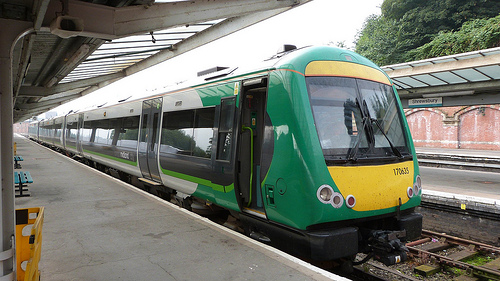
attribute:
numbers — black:
[390, 165, 410, 176]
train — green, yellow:
[26, 43, 427, 261]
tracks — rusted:
[393, 228, 484, 274]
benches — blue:
[14, 151, 27, 192]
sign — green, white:
[405, 95, 445, 110]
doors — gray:
[134, 96, 164, 185]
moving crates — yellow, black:
[16, 203, 37, 279]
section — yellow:
[330, 162, 411, 209]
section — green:
[263, 72, 334, 237]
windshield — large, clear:
[309, 76, 409, 164]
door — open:
[235, 80, 264, 213]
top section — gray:
[30, 56, 310, 107]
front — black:
[311, 213, 429, 266]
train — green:
[267, 43, 434, 269]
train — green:
[210, 33, 480, 278]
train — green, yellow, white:
[102, 80, 469, 267]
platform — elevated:
[32, 131, 238, 275]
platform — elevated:
[412, 152, 499, 198]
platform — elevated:
[420, 155, 494, 215]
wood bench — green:
[14, 159, 35, 216]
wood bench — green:
[14, 148, 30, 169]